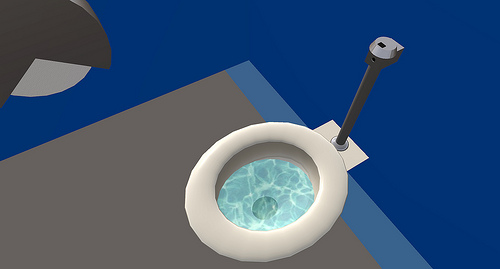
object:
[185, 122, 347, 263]
seat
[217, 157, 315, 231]
water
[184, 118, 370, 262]
toilet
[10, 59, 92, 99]
paper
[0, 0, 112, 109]
dispenser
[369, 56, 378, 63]
sensor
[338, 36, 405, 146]
post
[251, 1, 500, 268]
wall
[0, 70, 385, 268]
floor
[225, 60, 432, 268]
line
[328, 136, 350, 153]
ring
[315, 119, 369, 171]
square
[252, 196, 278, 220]
hole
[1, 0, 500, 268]
bathroom